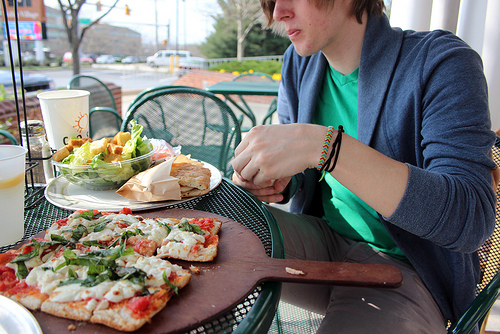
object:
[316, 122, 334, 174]
bracelet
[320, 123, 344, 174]
bracelet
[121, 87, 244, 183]
chair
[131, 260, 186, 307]
slice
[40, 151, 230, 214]
plate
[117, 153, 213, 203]
sandwich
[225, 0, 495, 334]
person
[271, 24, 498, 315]
sweater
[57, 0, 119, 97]
tree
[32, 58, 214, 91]
road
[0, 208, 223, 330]
pizza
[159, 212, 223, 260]
square slice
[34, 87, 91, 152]
cup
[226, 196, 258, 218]
table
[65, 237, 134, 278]
green veggies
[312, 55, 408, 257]
shirt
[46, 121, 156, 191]
salad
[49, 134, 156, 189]
bowl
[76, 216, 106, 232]
spinach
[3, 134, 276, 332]
table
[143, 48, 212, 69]
van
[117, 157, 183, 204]
bag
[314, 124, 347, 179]
wrist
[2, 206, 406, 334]
tray